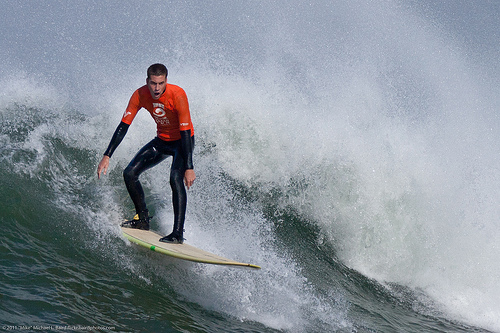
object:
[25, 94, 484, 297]
wave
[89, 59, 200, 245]
man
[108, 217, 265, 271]
surfboard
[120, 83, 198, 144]
t-shirt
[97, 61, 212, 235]
body suit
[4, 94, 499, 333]
ocean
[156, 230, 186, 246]
surf shoe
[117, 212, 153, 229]
surf shoe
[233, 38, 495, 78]
mist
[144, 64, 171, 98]
head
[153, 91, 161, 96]
mouth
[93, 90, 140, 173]
right arm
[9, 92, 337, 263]
wave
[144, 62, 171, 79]
hair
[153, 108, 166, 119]
logo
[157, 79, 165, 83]
eye brow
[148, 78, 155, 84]
eye brow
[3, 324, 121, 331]
lettering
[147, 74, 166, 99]
face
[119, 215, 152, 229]
right foot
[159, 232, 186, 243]
left foot